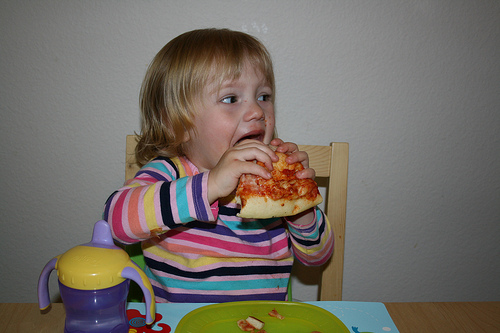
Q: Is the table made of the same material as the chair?
A: Yes, both the table and the chair are made of wood.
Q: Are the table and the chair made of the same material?
A: Yes, both the table and the chair are made of wood.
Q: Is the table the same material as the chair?
A: Yes, both the table and the chair are made of wood.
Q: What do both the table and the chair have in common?
A: The material, both the table and the chair are wooden.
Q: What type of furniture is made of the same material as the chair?
A: The table is made of the same material as the chair.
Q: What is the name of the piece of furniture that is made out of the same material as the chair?
A: The piece of furniture is a table.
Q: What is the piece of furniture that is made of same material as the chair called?
A: The piece of furniture is a table.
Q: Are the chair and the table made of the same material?
A: Yes, both the chair and the table are made of wood.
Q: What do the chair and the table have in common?
A: The material, both the chair and the table are wooden.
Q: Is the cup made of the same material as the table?
A: No, the cup is made of plastic and the table is made of wood.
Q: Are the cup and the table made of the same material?
A: No, the cup is made of plastic and the table is made of wood.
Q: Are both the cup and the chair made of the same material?
A: No, the cup is made of plastic and the chair is made of wood.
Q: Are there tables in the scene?
A: Yes, there is a table.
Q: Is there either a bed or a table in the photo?
A: Yes, there is a table.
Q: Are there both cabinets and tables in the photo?
A: No, there is a table but no cabinets.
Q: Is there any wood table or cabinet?
A: Yes, there is a wood table.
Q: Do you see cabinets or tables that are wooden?
A: Yes, the table is wooden.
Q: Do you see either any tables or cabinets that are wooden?
A: Yes, the table is wooden.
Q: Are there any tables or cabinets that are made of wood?
A: Yes, the table is made of wood.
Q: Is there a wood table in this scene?
A: Yes, there is a wood table.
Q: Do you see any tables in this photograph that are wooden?
A: Yes, there is a wood table.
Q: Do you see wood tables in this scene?
A: Yes, there is a wood table.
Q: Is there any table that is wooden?
A: Yes, there is a table that is wooden.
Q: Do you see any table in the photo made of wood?
A: Yes, there is a table that is made of wood.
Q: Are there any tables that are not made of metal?
A: Yes, there is a table that is made of wood.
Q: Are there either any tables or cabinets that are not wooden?
A: No, there is a table but it is wooden.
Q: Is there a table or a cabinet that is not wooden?
A: No, there is a table but it is wooden.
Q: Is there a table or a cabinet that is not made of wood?
A: No, there is a table but it is made of wood.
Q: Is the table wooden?
A: Yes, the table is wooden.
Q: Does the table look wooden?
A: Yes, the table is wooden.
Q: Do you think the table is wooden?
A: Yes, the table is wooden.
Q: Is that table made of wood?
A: Yes, the table is made of wood.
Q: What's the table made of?
A: The table is made of wood.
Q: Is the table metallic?
A: No, the table is wooden.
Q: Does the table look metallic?
A: No, the table is wooden.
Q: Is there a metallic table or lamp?
A: No, there is a table but it is wooden.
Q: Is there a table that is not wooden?
A: No, there is a table but it is wooden.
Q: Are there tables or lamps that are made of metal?
A: No, there is a table but it is made of wood.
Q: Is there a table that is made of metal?
A: No, there is a table but it is made of wood.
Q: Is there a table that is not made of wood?
A: No, there is a table but it is made of wood.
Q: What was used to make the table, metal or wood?
A: The table is made of wood.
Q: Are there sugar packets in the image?
A: No, there are no sugar packets.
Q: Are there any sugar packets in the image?
A: No, there are no sugar packets.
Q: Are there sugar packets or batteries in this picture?
A: No, there are no sugar packets or batteries.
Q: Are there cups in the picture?
A: Yes, there is a cup.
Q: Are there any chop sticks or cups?
A: Yes, there is a cup.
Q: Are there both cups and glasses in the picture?
A: No, there is a cup but no glasses.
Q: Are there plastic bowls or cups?
A: Yes, there is a plastic cup.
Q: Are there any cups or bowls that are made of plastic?
A: Yes, the cup is made of plastic.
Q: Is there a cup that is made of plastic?
A: Yes, there is a cup that is made of plastic.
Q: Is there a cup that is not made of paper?
A: Yes, there is a cup that is made of plastic.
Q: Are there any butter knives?
A: No, there are no butter knives.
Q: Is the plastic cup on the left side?
A: Yes, the cup is on the left of the image.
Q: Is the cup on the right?
A: No, the cup is on the left of the image.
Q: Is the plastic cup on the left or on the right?
A: The cup is on the left of the image.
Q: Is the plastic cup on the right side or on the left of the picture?
A: The cup is on the left of the image.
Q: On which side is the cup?
A: The cup is on the left of the image.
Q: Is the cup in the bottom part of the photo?
A: Yes, the cup is in the bottom of the image.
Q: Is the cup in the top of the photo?
A: No, the cup is in the bottom of the image.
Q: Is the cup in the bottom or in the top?
A: The cup is in the bottom of the image.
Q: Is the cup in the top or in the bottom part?
A: The cup is in the bottom of the image.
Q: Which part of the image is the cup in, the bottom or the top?
A: The cup is in the bottom of the image.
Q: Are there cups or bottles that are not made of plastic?
A: No, there is a cup but it is made of plastic.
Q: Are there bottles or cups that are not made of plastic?
A: No, there is a cup but it is made of plastic.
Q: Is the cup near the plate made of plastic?
A: Yes, the cup is made of plastic.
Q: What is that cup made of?
A: The cup is made of plastic.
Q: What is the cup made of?
A: The cup is made of plastic.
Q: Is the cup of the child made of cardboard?
A: No, the cup is made of plastic.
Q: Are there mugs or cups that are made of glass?
A: No, there is a cup but it is made of plastic.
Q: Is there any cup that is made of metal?
A: No, there is a cup but it is made of plastic.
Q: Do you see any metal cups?
A: No, there is a cup but it is made of plastic.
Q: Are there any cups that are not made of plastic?
A: No, there is a cup but it is made of plastic.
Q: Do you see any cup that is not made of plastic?
A: No, there is a cup but it is made of plastic.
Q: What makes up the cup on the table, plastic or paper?
A: The cup is made of plastic.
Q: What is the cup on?
A: The cup is on the table.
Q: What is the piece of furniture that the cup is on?
A: The piece of furniture is a table.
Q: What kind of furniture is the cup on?
A: The cup is on the table.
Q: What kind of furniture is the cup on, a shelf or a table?
A: The cup is on a table.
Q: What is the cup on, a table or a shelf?
A: The cup is on a table.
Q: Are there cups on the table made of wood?
A: Yes, there is a cup on the table.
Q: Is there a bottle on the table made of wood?
A: No, there is a cup on the table.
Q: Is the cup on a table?
A: Yes, the cup is on a table.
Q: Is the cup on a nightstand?
A: No, the cup is on a table.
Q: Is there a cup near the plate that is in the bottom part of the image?
A: Yes, there is a cup near the plate.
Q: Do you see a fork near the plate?
A: No, there is a cup near the plate.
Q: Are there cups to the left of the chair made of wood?
A: Yes, there is a cup to the left of the chair.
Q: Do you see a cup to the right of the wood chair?
A: No, the cup is to the left of the chair.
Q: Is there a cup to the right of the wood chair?
A: No, the cup is to the left of the chair.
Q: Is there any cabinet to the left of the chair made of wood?
A: No, there is a cup to the left of the chair.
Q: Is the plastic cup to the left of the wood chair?
A: Yes, the cup is to the left of the chair.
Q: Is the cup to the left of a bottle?
A: No, the cup is to the left of the chair.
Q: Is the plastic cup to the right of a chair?
A: No, the cup is to the left of a chair.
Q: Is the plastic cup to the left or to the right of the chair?
A: The cup is to the left of the chair.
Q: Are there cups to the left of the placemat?
A: Yes, there is a cup to the left of the placemat.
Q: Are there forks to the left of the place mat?
A: No, there is a cup to the left of the place mat.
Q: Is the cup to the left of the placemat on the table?
A: Yes, the cup is to the left of the placemat.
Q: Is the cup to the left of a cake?
A: No, the cup is to the left of the placemat.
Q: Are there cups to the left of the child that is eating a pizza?
A: Yes, there is a cup to the left of the kid.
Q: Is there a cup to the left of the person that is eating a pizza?
A: Yes, there is a cup to the left of the kid.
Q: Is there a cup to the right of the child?
A: No, the cup is to the left of the child.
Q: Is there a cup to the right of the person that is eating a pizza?
A: No, the cup is to the left of the child.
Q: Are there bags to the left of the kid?
A: No, there is a cup to the left of the kid.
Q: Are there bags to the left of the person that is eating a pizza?
A: No, there is a cup to the left of the kid.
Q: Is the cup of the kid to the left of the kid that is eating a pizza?
A: Yes, the cup is to the left of the kid.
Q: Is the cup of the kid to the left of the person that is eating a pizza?
A: Yes, the cup is to the left of the kid.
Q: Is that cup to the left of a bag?
A: No, the cup is to the left of the kid.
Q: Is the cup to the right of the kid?
A: No, the cup is to the left of the kid.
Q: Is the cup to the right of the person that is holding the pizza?
A: No, the cup is to the left of the kid.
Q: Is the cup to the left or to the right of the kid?
A: The cup is to the left of the kid.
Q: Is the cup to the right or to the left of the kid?
A: The cup is to the left of the kid.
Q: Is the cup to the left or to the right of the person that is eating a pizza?
A: The cup is to the left of the kid.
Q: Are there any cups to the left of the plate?
A: Yes, there is a cup to the left of the plate.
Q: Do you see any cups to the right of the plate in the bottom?
A: No, the cup is to the left of the plate.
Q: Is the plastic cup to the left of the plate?
A: Yes, the cup is to the left of the plate.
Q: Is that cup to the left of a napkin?
A: No, the cup is to the left of the plate.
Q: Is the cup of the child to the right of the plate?
A: No, the cup is to the left of the plate.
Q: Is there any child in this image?
A: Yes, there is a child.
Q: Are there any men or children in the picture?
A: Yes, there is a child.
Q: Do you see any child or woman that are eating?
A: Yes, the child is eating.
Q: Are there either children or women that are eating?
A: Yes, the child is eating.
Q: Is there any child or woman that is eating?
A: Yes, the child is eating.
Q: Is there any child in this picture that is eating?
A: Yes, there is a child that is eating.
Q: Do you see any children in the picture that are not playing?
A: Yes, there is a child that is eating .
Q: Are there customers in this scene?
A: No, there are no customers.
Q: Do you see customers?
A: No, there are no customers.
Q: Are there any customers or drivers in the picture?
A: No, there are no customers or drivers.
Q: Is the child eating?
A: Yes, the child is eating.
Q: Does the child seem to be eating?
A: Yes, the child is eating.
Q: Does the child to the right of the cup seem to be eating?
A: Yes, the child is eating.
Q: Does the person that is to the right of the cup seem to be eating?
A: Yes, the child is eating.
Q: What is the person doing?
A: The child is eating.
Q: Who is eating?
A: The child is eating.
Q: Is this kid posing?
A: No, the kid is eating.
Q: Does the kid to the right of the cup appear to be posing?
A: No, the child is eating.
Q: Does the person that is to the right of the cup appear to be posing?
A: No, the child is eating.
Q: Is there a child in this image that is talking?
A: No, there is a child but he is eating.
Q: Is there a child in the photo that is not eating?
A: No, there is a child but he is eating.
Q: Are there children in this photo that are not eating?
A: No, there is a child but he is eating.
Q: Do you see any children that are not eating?
A: No, there is a child but he is eating.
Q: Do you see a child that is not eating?
A: No, there is a child but he is eating.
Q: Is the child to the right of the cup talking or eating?
A: The kid is eating.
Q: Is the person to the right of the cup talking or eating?
A: The kid is eating.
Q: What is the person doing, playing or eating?
A: The child is eating.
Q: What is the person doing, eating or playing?
A: The child is eating.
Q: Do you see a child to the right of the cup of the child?
A: Yes, there is a child to the right of the cup.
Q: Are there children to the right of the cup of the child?
A: Yes, there is a child to the right of the cup.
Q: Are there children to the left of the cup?
A: No, the child is to the right of the cup.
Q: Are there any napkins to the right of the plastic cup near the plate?
A: No, there is a child to the right of the cup.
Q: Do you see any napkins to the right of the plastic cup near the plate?
A: No, there is a child to the right of the cup.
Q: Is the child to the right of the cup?
A: Yes, the child is to the right of the cup.